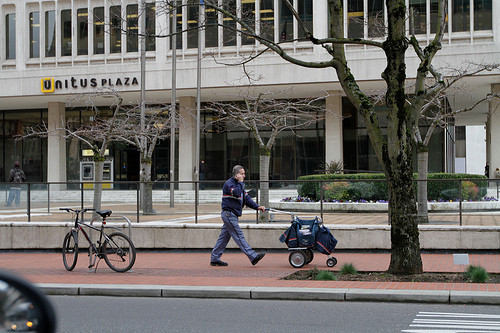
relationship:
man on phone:
[209, 163, 268, 267] [235, 173, 240, 177]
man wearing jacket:
[209, 163, 268, 267] [220, 177, 259, 217]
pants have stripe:
[209, 208, 261, 262] [225, 211, 253, 257]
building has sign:
[2, 1, 497, 187] [39, 75, 140, 94]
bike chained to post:
[56, 205, 139, 273] [89, 213, 134, 267]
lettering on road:
[400, 310, 499, 332] [32, 291, 500, 332]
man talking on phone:
[209, 163, 268, 267] [235, 173, 240, 177]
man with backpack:
[6, 160, 29, 206] [12, 168, 24, 183]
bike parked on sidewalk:
[56, 205, 139, 273] [0, 248, 499, 292]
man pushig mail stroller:
[209, 163, 268, 267] [279, 213, 338, 267]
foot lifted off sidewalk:
[250, 250, 268, 266] [0, 248, 499, 292]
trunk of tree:
[366, 134, 428, 280] [109, 0, 500, 276]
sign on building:
[39, 75, 140, 94] [2, 1, 497, 187]